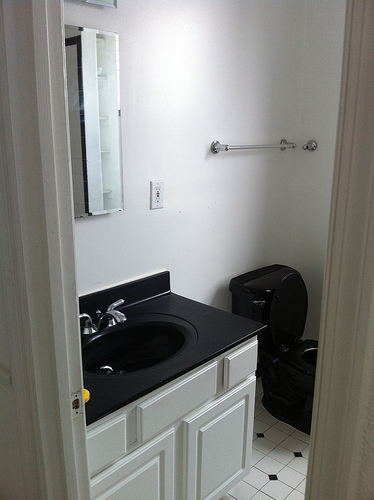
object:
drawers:
[136, 359, 218, 447]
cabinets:
[182, 375, 257, 498]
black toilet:
[228, 262, 319, 434]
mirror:
[65, 25, 90, 217]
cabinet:
[64, 23, 126, 219]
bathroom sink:
[81, 318, 191, 375]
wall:
[30, 0, 304, 365]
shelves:
[99, 118, 111, 123]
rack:
[212, 140, 295, 155]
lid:
[268, 269, 309, 344]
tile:
[260, 475, 296, 499]